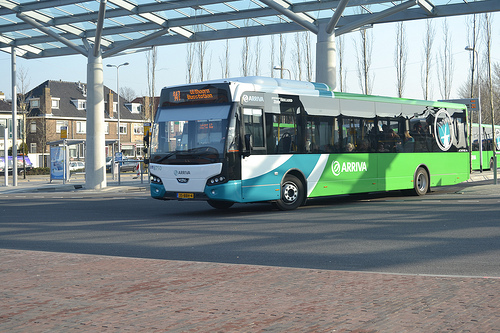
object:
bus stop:
[47, 136, 75, 185]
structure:
[83, 35, 111, 186]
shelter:
[0, 1, 500, 249]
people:
[277, 127, 300, 151]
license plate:
[174, 191, 192, 200]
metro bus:
[141, 74, 473, 210]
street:
[1, 177, 499, 333]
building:
[0, 93, 25, 170]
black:
[222, 154, 243, 180]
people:
[342, 139, 363, 151]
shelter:
[50, 161, 68, 190]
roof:
[56, 136, 84, 142]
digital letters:
[170, 87, 210, 103]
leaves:
[482, 113, 495, 122]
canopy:
[478, 104, 493, 113]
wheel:
[280, 168, 311, 210]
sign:
[167, 87, 225, 101]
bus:
[145, 75, 474, 212]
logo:
[330, 160, 370, 178]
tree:
[483, 11, 500, 184]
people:
[378, 122, 406, 152]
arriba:
[339, 159, 374, 177]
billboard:
[47, 139, 69, 181]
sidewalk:
[1, 250, 499, 332]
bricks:
[319, 301, 355, 321]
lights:
[208, 175, 224, 186]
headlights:
[209, 175, 224, 185]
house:
[15, 79, 148, 170]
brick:
[42, 126, 48, 130]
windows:
[73, 97, 88, 111]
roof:
[22, 79, 136, 111]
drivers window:
[239, 114, 270, 153]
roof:
[0, 0, 500, 55]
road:
[4, 179, 499, 332]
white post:
[0, 117, 12, 187]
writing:
[172, 169, 193, 187]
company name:
[329, 158, 372, 178]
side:
[241, 87, 468, 205]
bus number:
[169, 88, 182, 106]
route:
[182, 86, 219, 101]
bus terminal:
[3, 2, 495, 306]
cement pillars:
[83, 49, 108, 188]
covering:
[0, 0, 498, 80]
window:
[149, 100, 231, 157]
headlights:
[146, 174, 159, 186]